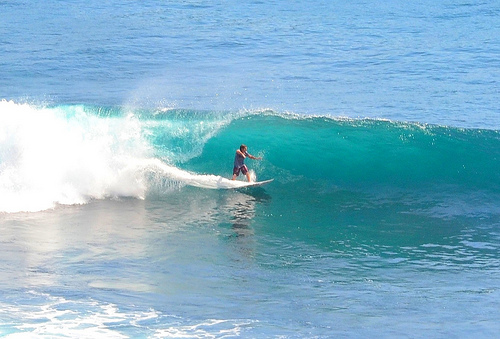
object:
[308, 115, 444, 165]
waves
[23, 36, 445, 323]
ocean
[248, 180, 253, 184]
person's feet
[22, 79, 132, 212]
water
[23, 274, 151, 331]
foam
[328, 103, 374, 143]
part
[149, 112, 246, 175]
part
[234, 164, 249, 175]
shorts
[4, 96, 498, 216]
wave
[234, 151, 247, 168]
shirt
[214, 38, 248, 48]
ripple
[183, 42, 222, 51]
ripple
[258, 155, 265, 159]
hand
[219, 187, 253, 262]
reflection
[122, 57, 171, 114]
mist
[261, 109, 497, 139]
top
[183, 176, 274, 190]
board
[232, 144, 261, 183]
guy